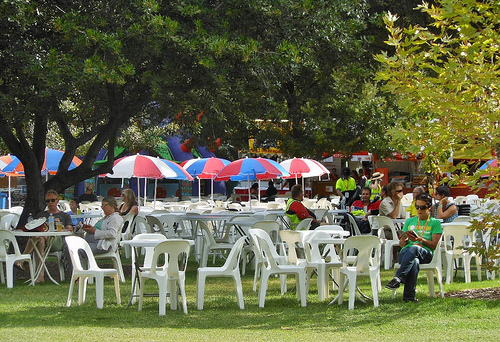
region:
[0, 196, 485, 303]
White plastic chairs on the lawn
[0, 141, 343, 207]
Umbrellas raised for sun protection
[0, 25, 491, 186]
Green leaves on the trees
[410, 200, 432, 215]
Sunglasses on the person's face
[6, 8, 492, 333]
Photo taken during the day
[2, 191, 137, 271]
People sitting in the shade of a tree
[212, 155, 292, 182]
Blue and red umbrella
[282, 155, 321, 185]
Red and white umbrella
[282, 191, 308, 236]
Safety vest on the man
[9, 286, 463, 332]
Shadows from the tree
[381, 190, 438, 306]
Man sitting in chair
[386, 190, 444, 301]
Man reading a book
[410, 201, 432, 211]
Sunglasses on man's face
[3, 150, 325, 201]
Line of open shade umbrellas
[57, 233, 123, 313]
White plastic chair in park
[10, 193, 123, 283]
People eating lunch in park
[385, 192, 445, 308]
Man seated with legs crossed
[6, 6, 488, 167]
Trees with summer leaf coverage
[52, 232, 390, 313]
Empty plastic chairs in park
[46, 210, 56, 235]
Plastic water bottle on table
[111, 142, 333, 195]
umbrellas above chairs and tables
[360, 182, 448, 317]
man sitting on white chair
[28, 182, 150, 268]
people sitting outside on chairs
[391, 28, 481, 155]
green leaves on a tree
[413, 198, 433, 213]
sunglasses on a man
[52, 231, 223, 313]
white chairs in the grass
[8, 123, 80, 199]
trunk of a tree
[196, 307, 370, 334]
shadow casted on the grass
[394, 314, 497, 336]
green grass on the ground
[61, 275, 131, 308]
legs of a chair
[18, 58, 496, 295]
a public event in a park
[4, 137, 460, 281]
a lot of white chairs and tables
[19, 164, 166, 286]
people sitting at a table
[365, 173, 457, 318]
this person has an object in their hand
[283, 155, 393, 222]
these people are workers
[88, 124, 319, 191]
red, white and blue beach umbrellas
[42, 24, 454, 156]
trees above the ground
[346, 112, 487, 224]
people at an event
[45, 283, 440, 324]
green grass beneath the tables and chairs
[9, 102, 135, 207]
a tree branch over the people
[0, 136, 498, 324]
People at an outdoor event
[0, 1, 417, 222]
Dark green trees in the background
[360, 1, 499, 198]
Tree with light green trees to the left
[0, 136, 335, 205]
Shade umbrellas attached to tables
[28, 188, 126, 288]
Man and woman sitting at the table to the left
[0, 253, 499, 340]
Grassy area that the tables are sitting on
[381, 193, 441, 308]
Person in a green shirt reading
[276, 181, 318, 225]
Man with flourescent green vest and red shirt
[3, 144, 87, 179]
Orange and blue umbrella to the left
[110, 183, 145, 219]
Blond woman in black shirt looking left